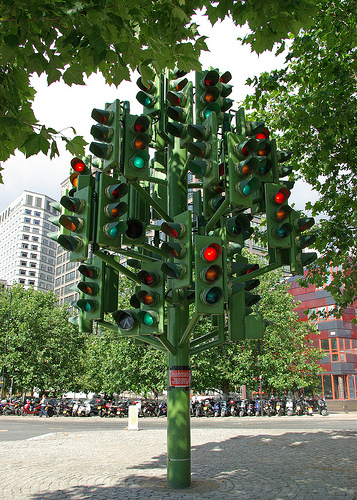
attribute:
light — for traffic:
[193, 232, 223, 315]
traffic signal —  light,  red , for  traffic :
[241, 98, 314, 215]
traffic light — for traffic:
[226, 131, 258, 196]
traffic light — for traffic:
[263, 182, 291, 250]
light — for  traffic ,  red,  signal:
[193, 66, 221, 133]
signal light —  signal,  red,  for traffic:
[271, 190, 285, 204]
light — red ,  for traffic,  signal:
[199, 241, 223, 263]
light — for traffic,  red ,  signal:
[240, 143, 250, 153]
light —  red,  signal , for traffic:
[141, 271, 157, 281]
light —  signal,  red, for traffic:
[180, 71, 231, 124]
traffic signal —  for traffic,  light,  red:
[65, 153, 92, 193]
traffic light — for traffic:
[69, 259, 105, 330]